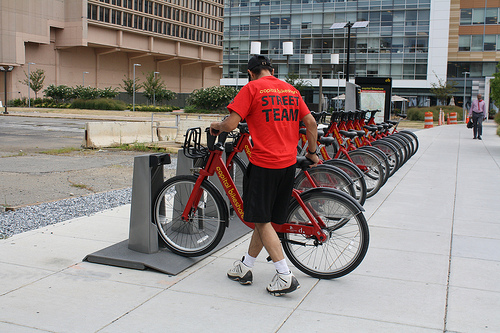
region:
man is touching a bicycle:
[205, 52, 323, 298]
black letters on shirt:
[258, 92, 299, 129]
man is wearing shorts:
[239, 157, 291, 226]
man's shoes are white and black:
[225, 257, 301, 296]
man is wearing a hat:
[245, 52, 277, 79]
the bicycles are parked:
[73, 106, 420, 278]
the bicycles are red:
[157, 103, 421, 286]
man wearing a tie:
[475, 100, 482, 113]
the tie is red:
[475, 101, 485, 113]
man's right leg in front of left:
[224, 220, 267, 287]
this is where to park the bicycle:
[105, 110, 451, 280]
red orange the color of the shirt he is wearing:
[218, 82, 319, 193]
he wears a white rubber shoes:
[227, 254, 312, 317]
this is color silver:
[111, 149, 182, 293]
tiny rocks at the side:
[36, 189, 120, 219]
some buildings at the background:
[51, 0, 496, 75]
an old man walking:
[468, 84, 490, 142]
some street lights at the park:
[6, 53, 176, 125]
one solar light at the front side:
[326, 17, 378, 98]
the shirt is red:
[264, 130, 283, 155]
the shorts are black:
[253, 184, 270, 221]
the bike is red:
[205, 159, 222, 179]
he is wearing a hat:
[246, 55, 268, 75]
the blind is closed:
[311, 16, 323, 32]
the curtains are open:
[311, 38, 341, 50]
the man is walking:
[466, 90, 485, 145]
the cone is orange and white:
[420, 106, 437, 131]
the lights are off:
[247, 34, 315, 66]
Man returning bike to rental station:
[154, 54, 371, 296]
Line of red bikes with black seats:
[152, 109, 419, 280]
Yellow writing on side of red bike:
[214, 166, 246, 220]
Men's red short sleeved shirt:
[226, 74, 311, 169]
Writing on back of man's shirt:
[260, 87, 300, 123]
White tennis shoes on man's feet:
[225, 262, 299, 297]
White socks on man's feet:
[241, 254, 291, 273]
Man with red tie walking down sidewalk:
[464, 91, 489, 141]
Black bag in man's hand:
[466, 119, 472, 128]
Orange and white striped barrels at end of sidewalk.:
[420, 108, 457, 131]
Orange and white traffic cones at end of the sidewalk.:
[432, 107, 472, 129]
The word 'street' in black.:
[257, 95, 300, 105]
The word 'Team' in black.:
[264, 108, 299, 123]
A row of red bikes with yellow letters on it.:
[157, 107, 419, 279]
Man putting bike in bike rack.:
[211, 53, 321, 295]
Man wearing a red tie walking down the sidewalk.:
[466, 93, 487, 139]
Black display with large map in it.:
[357, 76, 394, 123]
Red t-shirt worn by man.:
[225, 75, 309, 172]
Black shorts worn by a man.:
[241, 160, 297, 225]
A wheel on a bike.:
[287, 190, 371, 284]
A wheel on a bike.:
[156, 170, 219, 255]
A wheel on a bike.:
[327, 155, 378, 201]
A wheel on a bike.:
[364, 148, 394, 189]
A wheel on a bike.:
[373, 139, 395, 178]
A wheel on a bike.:
[381, 135, 404, 169]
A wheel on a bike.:
[388, 130, 408, 164]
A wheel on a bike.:
[395, 131, 413, 159]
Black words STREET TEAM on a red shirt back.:
[261, 94, 301, 121]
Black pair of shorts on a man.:
[241, 159, 298, 224]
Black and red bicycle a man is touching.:
[152, 127, 370, 280]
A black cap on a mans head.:
[244, 54, 272, 82]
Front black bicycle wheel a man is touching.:
[151, 174, 228, 258]